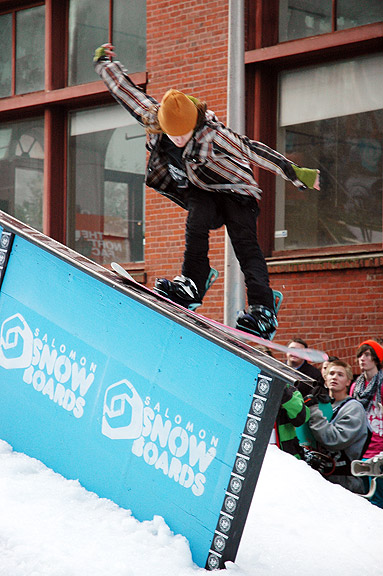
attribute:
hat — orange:
[155, 88, 197, 136]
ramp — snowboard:
[2, 198, 321, 572]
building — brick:
[1, 6, 377, 515]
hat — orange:
[153, 84, 197, 135]